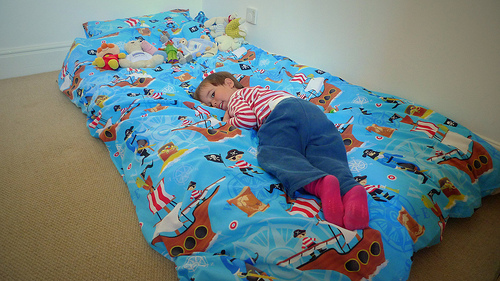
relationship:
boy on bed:
[192, 70, 370, 231] [53, 6, 497, 278]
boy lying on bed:
[192, 70, 370, 231] [53, 6, 497, 278]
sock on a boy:
[342, 184, 370, 230] [192, 70, 370, 231]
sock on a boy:
[304, 175, 345, 228] [192, 70, 370, 231]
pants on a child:
[256, 97, 364, 200] [193, 62, 378, 240]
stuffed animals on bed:
[91, 12, 253, 70] [53, 6, 497, 278]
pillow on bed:
[82, 8, 194, 39] [74, 16, 499, 235]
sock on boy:
[304, 175, 345, 228] [195, 72, 375, 232]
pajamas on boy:
[258, 100, 353, 189] [195, 72, 375, 232]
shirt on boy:
[227, 83, 291, 131] [195, 72, 375, 232]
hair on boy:
[197, 64, 238, 86] [195, 72, 375, 232]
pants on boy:
[256, 97, 363, 199] [192, 70, 370, 231]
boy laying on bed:
[192, 70, 370, 231] [53, 6, 497, 278]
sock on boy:
[308, 167, 346, 232] [192, 70, 370, 231]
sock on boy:
[343, 182, 373, 234] [192, 70, 370, 231]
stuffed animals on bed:
[91, 10, 248, 70] [53, 6, 497, 278]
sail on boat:
[143, 170, 178, 222] [151, 181, 223, 264]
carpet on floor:
[4, 77, 160, 279] [6, 77, 176, 279]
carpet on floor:
[401, 198, 498, 275] [414, 189, 499, 277]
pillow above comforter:
[41, 23, 201, 55] [136, 27, 488, 265]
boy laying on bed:
[192, 70, 370, 231] [68, 15, 495, 267]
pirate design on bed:
[67, 12, 497, 277] [71, 35, 399, 205]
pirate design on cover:
[67, 12, 497, 277] [66, 7, 497, 279]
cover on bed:
[66, 7, 497, 279] [71, 35, 399, 205]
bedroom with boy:
[0, 1, 498, 278] [192, 70, 370, 231]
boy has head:
[192, 70, 370, 231] [186, 61, 247, 118]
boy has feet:
[192, 70, 370, 231] [321, 176, 367, 230]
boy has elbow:
[192, 70, 370, 231] [219, 103, 256, 123]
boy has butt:
[192, 70, 370, 231] [271, 96, 341, 136]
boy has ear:
[192, 70, 370, 231] [223, 76, 240, 89]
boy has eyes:
[192, 70, 370, 231] [205, 76, 227, 117]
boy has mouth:
[192, 70, 370, 231] [217, 97, 225, 107]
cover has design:
[66, 7, 497, 279] [159, 210, 215, 250]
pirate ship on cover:
[289, 220, 392, 274] [66, 7, 497, 279]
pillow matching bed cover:
[75, 7, 189, 36] [121, 84, 267, 221]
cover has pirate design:
[66, 7, 497, 279] [67, 12, 498, 281]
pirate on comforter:
[347, 169, 400, 212] [48, 5, 499, 277]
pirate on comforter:
[283, 215, 323, 256] [48, 5, 499, 277]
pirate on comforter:
[179, 175, 206, 207] [48, 5, 499, 277]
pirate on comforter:
[218, 141, 266, 181] [48, 5, 499, 277]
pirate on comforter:
[137, 84, 174, 106] [48, 5, 499, 277]